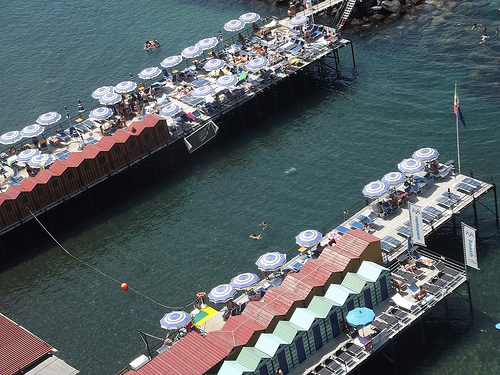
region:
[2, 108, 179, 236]
a row of cabanas for changing clothes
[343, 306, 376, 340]
this umbrella is a light aqua color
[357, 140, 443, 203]
almost all the umbrellas are blue with white stripes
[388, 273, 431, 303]
sunbathers on the dock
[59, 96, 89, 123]
these umbrellas are closed and not in use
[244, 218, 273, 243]
swimmers having fun in the water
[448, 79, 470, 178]
a flag flies at the end of the dock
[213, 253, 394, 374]
cabanas are both red and blue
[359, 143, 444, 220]
people relax in the shade of the umbrellas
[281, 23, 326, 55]
empty lounge chairs waiting for sunbathers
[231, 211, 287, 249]
two people are swimming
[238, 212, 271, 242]
two people are swimming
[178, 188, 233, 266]
the water is green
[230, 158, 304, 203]
the water is green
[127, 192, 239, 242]
the water is green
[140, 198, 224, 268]
the water is green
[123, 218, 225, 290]
the water is green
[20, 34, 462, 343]
this is at a bay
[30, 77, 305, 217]
this is a dock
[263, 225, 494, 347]
this is a pier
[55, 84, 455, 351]
there are two piers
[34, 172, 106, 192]
these huts are red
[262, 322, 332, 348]
these huts are green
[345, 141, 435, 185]
these are umbrellas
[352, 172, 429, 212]
the umbrellas are gray and white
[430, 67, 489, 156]
this is a flag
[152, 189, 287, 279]
the water is green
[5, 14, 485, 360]
water with piers extending in it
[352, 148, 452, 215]
umbrellas over seating areas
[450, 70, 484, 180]
flag on end of pier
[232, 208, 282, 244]
people in the water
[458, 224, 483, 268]
banner at end of pier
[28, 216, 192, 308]
rope connecting two seating areas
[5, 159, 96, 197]
red structures along edge of pier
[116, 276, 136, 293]
ball in center of rope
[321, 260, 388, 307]
blue structures on deck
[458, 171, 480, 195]
lounges on the deck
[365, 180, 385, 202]
open umbrella on a dock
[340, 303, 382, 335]
open umbrella on a dock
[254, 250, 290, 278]
open umbrella on a dock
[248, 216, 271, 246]
two people swimming in the water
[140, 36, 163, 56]
a person in the water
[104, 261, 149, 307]
and orange bouy in the water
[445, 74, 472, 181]
a flag on a pole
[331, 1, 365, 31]
stairs leading from a dock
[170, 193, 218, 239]
calm body of water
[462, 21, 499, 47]
people swimming in the water